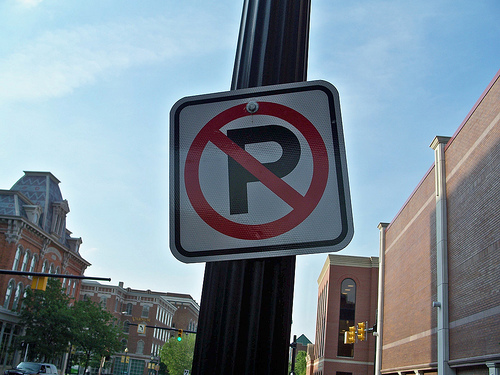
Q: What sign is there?
A: No parking.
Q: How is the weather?
A: Fair.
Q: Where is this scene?
A: City street.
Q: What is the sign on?
A: Post.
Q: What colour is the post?
A: Black.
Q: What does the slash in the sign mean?
A: NO.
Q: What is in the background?
A: Building.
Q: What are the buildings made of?
A: Brick.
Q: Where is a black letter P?
A: Sign on post.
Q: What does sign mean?
A: No parking.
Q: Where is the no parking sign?
A: Black metal pole.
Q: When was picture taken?
A: Afternoon.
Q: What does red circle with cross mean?
A: Do not park.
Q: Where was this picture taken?
A: City.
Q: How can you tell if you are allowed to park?
A: Red circle with cross over black P.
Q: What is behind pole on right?
A: Traffic lights.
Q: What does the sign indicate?
A: No parking.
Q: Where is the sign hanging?
A: From a pole.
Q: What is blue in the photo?
A: Sky.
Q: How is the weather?
A: Sunny.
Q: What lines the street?
A: Trees and buildings.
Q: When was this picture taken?
A: Daytime.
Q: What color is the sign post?
A: Black.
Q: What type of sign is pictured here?
A: No parking.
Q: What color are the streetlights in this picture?
A: Yellow.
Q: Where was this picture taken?
A: A city street.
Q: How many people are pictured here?
A: Zero.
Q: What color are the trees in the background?
A: Green.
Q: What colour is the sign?
A: Black red and white.